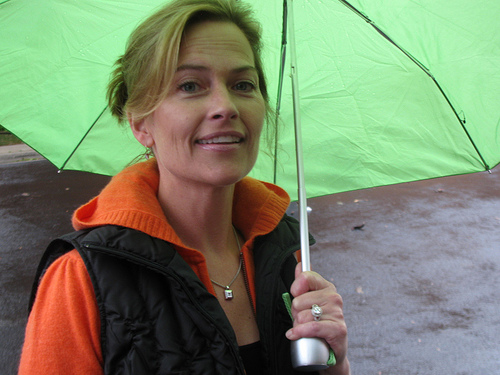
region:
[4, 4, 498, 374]
Woman is standing on the street.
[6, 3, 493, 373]
Woman is holding an umbrella.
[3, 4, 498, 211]
Umbrella is mint green.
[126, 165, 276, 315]
Woman is wearing a necklace.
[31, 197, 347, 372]
Woman is wearing a black vest.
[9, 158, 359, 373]
Woman is wearing orange sweater.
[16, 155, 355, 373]
Sweater has a hood.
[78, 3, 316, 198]
Woman has her hair up.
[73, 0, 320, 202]
Woman has blonde hair.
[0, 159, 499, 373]
Street is paved and wet.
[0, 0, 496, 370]
Woman holding a green umbrella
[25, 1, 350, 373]
woman with blonde hair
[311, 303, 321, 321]
female wedding ring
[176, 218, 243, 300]
necklace with a square pendant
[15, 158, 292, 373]
orange jacket with a hood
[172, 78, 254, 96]
smiling blue eyes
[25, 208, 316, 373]
black padded vest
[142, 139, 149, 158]
earring in right ear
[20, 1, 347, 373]
blonde woman with ring on her finger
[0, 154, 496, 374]
slick road after a rain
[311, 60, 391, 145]
Umbrella is green in color.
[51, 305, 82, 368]
Shirt is orange in color.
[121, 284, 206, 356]
Overcoat is black in color.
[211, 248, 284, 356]
Lady is wearing s silver chain.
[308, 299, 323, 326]
Lady is wearing s silver ring.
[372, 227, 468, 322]
Road is wet.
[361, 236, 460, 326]
Road is grey in color.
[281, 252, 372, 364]
Lady is holding the umbrella.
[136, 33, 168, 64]
Hair is blonde in color.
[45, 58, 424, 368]
Daytime picture.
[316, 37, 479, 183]
Umbrella is green in color.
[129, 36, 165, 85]
Hair is blonde in color.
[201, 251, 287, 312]
Lady is wearing a silver chain.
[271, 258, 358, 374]
Lady is holding umbrella.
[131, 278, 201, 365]
Over coat is black in color.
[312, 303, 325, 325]
Lady is wearing a silver ring.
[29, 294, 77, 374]
Shirt color is orange.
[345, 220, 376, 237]
black spot on ground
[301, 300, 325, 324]
large sparkling diamond ring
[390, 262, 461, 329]
large grooves on groound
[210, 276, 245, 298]
silver necklace around woman's neck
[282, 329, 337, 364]
broad silver base on umbrella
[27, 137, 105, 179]
black spine in green umbrella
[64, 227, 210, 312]
black woman's vest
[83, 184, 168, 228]
orange sweater with hood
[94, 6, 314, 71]
blond hair on woman's head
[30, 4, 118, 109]
green umbrella